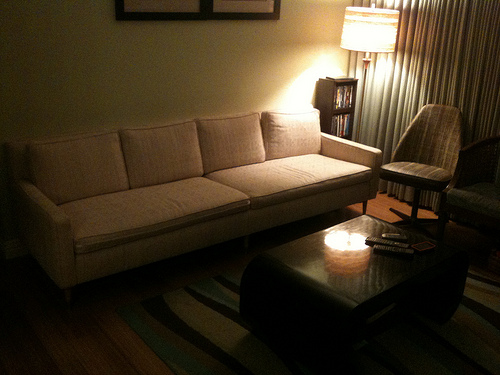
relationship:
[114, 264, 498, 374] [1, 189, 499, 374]
rug on top of floor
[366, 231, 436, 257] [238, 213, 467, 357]
remote controls on top of coffee table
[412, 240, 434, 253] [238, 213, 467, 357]
tablet on top of coffee table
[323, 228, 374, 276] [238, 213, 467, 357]
light reflection cast on coffee table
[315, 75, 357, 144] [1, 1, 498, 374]
bookshelf in corner of living room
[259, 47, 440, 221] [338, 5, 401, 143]
light streaming from floor lamp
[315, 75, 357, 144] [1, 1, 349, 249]
bookshelf leaning against wall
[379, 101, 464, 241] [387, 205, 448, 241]
chair has wheels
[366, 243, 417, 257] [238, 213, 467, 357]
remote controls sitting on coffee table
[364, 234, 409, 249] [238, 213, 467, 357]
remote control sitting on coffee table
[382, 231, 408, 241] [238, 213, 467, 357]
remote control sitting on coffee table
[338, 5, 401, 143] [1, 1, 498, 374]
floor lamp in corner of living room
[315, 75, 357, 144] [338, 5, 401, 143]
bookshelf next to floor lamp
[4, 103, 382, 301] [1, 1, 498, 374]
couch inside of living room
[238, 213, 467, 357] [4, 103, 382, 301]
coffee table in front of couch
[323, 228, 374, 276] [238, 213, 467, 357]
light reflection on top of coffee table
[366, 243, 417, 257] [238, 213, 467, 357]
remote controls on top of coffee table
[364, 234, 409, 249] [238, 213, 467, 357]
remote control on top of coffee table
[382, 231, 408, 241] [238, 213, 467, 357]
remote control on top of coffee table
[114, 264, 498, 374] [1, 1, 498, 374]
rug inside of living room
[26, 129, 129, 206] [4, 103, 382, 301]
cushion on back of couch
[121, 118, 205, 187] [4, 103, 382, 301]
cushion on back of couch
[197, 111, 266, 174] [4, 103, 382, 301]
cushion on back of couch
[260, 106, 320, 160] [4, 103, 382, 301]
cushion on back of couch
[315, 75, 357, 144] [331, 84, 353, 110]
bookshelf filled with dvds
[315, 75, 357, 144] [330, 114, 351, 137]
bookshelf filled with dvds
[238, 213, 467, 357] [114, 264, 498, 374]
coffee table on top of rug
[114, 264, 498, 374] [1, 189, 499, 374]
rug covering floor